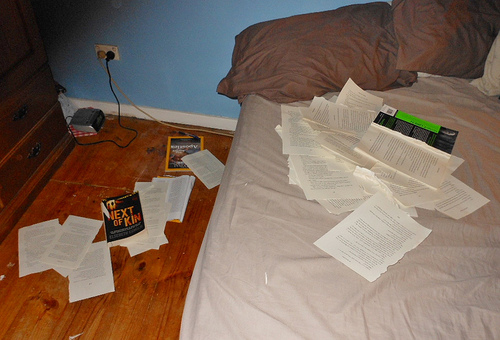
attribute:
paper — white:
[309, 190, 436, 283]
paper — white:
[356, 117, 454, 191]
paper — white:
[286, 150, 367, 202]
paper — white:
[422, 168, 488, 221]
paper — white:
[334, 72, 385, 113]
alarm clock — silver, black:
[61, 102, 103, 132]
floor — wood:
[1, 100, 241, 338]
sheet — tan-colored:
[250, 180, 270, 272]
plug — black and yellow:
[105, 52, 117, 61]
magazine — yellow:
[165, 130, 204, 175]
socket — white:
[91, 41, 121, 62]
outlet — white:
[91, 40, 123, 63]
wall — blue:
[36, 0, 231, 123]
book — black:
[102, 191, 149, 245]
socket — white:
[88, 44, 126, 69]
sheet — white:
[176, 71, 499, 338]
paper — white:
[275, 103, 473, 289]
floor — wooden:
[10, 298, 177, 335]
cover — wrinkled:
[219, 3, 446, 110]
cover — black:
[101, 187, 146, 245]